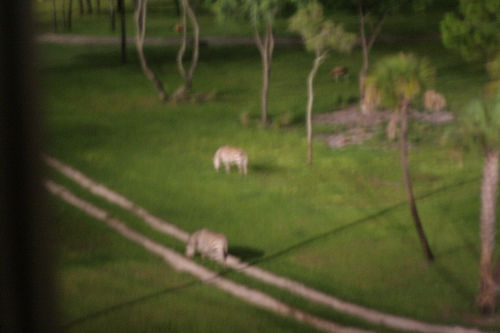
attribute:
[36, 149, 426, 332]
path — dirty, dirt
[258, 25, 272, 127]
trunk — large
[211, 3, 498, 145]
leaves — green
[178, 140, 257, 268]
zebra — grazing, brown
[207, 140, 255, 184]
animal — white, back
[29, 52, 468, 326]
grass — green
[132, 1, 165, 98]
trunk — crooked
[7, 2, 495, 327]
picture — blurry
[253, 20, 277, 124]
logs — brown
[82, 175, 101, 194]
grass — white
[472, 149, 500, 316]
tree — large